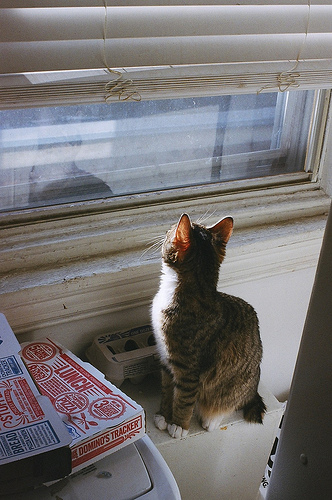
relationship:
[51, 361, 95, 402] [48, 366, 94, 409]
lunch on box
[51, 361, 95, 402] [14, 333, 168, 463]
lunch on box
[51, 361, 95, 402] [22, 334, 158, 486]
lunch on box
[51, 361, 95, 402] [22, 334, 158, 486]
lunch says on box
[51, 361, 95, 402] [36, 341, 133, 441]
lunch says on pizza box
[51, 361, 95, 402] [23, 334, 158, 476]
lunch says on box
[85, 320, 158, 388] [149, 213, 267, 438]
carton behind cat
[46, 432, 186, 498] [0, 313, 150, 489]
trash receptacle under boxes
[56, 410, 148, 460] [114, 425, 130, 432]
printed message seen part